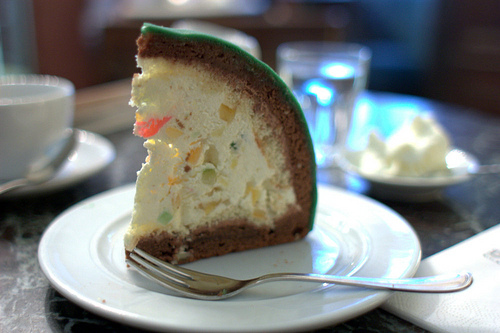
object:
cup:
[0, 74, 77, 182]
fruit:
[199, 167, 218, 186]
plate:
[0, 128, 117, 194]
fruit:
[154, 209, 172, 225]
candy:
[134, 112, 171, 140]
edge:
[124, 35, 145, 270]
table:
[0, 90, 499, 332]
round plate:
[330, 143, 480, 186]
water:
[280, 67, 367, 154]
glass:
[274, 40, 372, 171]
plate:
[36, 182, 420, 331]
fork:
[122, 247, 474, 300]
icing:
[358, 115, 447, 179]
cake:
[123, 22, 318, 270]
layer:
[123, 209, 309, 268]